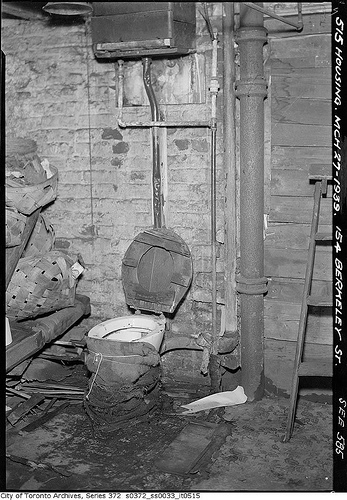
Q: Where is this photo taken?
A: Inside of a home.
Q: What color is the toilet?
A: Brown and white.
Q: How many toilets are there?
A: One.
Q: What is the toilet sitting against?
A: A wall.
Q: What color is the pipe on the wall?
A: Gray.